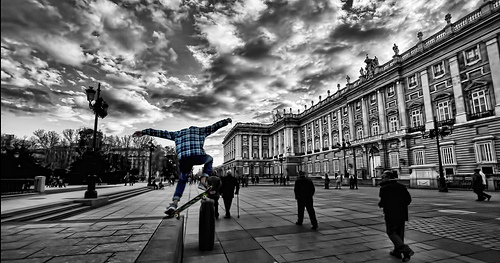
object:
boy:
[131, 116, 234, 216]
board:
[167, 179, 225, 215]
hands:
[130, 127, 147, 136]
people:
[375, 170, 424, 262]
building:
[221, 2, 499, 185]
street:
[180, 180, 500, 263]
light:
[428, 122, 452, 192]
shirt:
[137, 117, 231, 158]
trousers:
[166, 156, 216, 201]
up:
[169, 171, 211, 201]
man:
[217, 167, 240, 221]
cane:
[235, 192, 243, 219]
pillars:
[387, 36, 413, 131]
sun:
[152, 31, 233, 93]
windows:
[419, 57, 459, 126]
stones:
[291, 239, 362, 261]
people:
[467, 167, 493, 199]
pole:
[81, 81, 106, 198]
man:
[288, 171, 320, 229]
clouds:
[0, 3, 325, 80]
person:
[319, 175, 333, 191]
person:
[332, 175, 344, 188]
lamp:
[85, 86, 110, 115]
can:
[36, 174, 46, 196]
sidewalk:
[3, 171, 185, 259]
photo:
[0, 0, 498, 262]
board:
[196, 203, 220, 252]